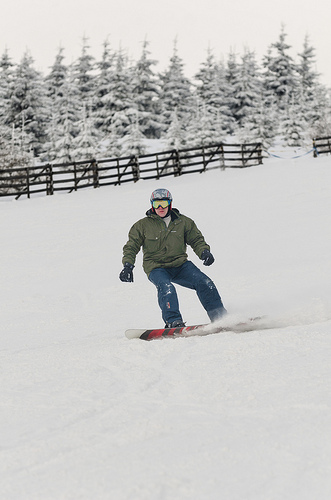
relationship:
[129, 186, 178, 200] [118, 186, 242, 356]
helmet on man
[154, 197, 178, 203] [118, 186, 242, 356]
goggles on man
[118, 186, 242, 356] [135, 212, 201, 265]
man in jacket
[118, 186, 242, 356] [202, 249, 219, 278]
man in gloves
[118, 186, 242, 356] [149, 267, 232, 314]
man in pants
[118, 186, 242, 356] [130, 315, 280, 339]
man on snowboard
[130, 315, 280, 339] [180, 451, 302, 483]
snowboard in snow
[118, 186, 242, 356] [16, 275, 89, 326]
man on ski slope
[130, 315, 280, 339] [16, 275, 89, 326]
snowboard on ski slope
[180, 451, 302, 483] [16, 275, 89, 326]
snow on ski slope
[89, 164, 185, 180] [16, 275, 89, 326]
fence by ski slope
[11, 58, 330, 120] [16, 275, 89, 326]
trees by ski slope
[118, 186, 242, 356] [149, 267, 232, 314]
man wearing pants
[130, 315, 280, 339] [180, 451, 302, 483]
snowboard on snow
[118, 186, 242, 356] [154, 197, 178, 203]
man in goggles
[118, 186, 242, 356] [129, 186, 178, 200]
man in helmet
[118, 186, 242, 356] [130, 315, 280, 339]
man riding snowboard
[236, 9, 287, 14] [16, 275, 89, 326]
sky over ski slope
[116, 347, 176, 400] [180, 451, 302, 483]
track marks in snow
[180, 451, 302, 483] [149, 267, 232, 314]
snow on pants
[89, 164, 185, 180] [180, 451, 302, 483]
fence in snow